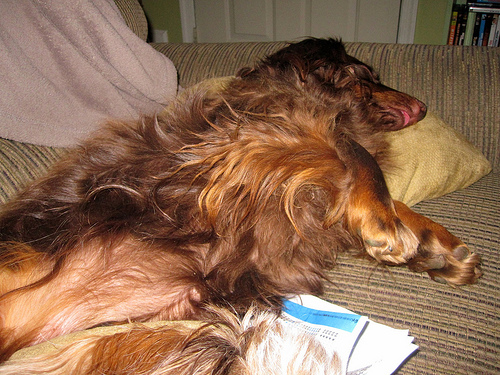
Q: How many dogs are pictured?
A: One.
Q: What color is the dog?
A: Brown.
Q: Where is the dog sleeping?
A: On a couch.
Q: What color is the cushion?
A: Yellow.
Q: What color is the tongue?
A: Pink.